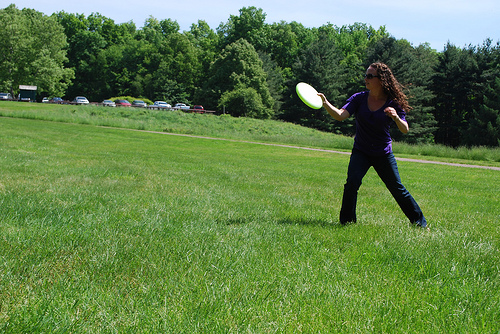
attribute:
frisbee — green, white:
[292, 76, 326, 114]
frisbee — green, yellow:
[290, 74, 328, 114]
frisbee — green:
[288, 76, 324, 110]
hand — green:
[315, 89, 331, 107]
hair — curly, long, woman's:
[368, 58, 411, 110]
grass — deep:
[101, 174, 275, 303]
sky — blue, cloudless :
[2, 1, 498, 31]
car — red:
[115, 92, 135, 112]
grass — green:
[6, 99, 495, 331]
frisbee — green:
[294, 80, 324, 108]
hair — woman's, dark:
[370, 61, 410, 111]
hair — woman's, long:
[371, 63, 412, 115]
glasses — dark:
[362, 74, 375, 82]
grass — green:
[2, 152, 332, 329]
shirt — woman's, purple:
[343, 90, 407, 148]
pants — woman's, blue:
[338, 149, 424, 222]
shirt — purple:
[343, 87, 405, 150]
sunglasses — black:
[360, 70, 380, 80]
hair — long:
[370, 57, 416, 110]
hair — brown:
[366, 58, 418, 115]